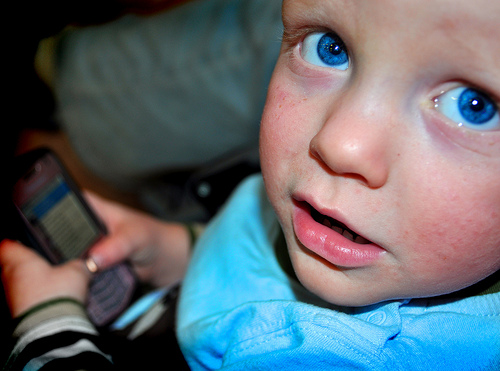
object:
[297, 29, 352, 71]
eye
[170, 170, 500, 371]
shirt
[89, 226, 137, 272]
finger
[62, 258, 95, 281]
finger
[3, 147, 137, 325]
screen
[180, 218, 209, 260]
sleeve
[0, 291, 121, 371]
sleeve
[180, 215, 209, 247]
stripes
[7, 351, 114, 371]
stripes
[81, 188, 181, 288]
hand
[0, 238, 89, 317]
hand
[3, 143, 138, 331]
cellphone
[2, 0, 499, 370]
boy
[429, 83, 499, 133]
eye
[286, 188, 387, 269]
mouth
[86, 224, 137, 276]
thumb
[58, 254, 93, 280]
thumb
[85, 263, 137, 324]
keyboard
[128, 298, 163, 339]
stripes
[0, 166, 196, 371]
shirt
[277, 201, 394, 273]
lips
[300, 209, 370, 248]
teeth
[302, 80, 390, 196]
nose